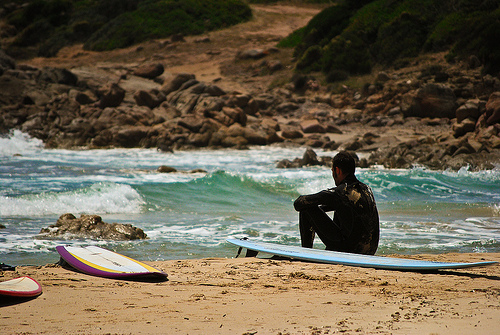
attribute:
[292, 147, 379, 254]
person — wet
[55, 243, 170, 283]
boogie board — purple, yellow, and white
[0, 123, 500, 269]
water — rippled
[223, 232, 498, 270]
surfboard — blue, long, light blue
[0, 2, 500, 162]
hill — rocky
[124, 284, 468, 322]
sand — wet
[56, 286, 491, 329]
sand — brown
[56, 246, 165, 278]
surfboard — white, yellow, purple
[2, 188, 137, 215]
water — white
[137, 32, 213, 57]
dirt — dry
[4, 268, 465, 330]
sand — brown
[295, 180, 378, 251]
wetsuit — black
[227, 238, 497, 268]
surfboard — blue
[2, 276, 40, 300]
surfboard — white, pink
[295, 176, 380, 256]
wetsuit — black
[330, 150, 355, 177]
hair — dark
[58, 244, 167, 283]
surfboard — purple, white, yellow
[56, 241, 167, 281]
surfboard — white, yellow, purple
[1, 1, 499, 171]
shore — rocky